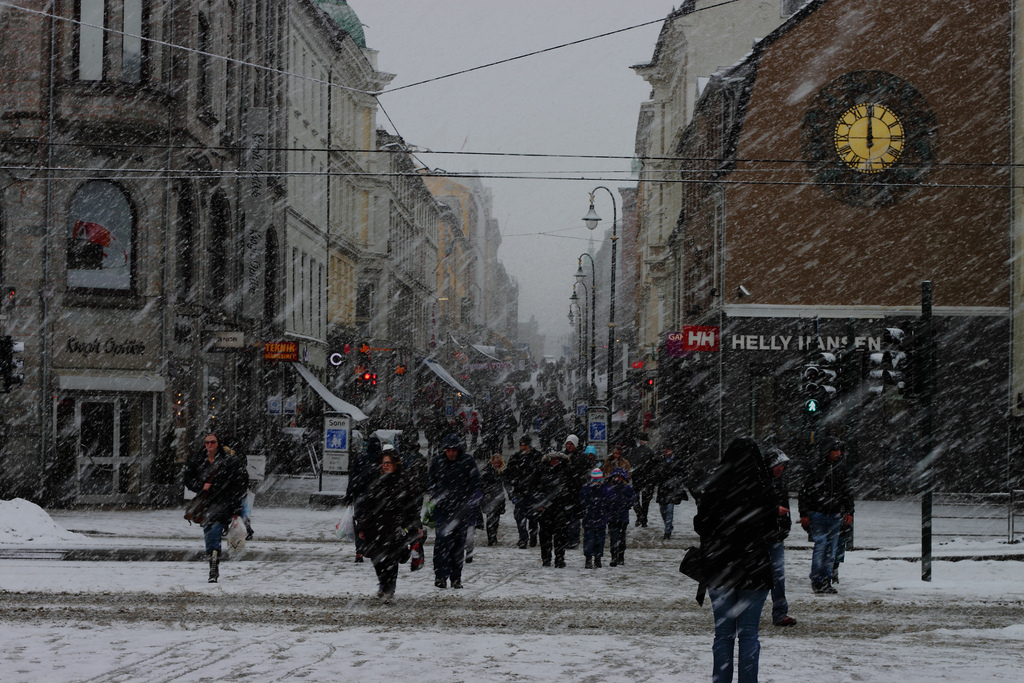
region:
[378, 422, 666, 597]
People walking across a snow covered street.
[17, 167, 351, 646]
Walking on a snowy day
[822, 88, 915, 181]
a yellow clock face with roman numerals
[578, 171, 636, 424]
a street light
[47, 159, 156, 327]
a rounded window in the snow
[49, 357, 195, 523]
shop doors in the snow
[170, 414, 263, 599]
a shopper in a black jacket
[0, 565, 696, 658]
tire tracks in the snow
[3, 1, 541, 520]
buildings on a snowy day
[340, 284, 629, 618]
shoppers on a busy street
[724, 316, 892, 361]
a shop sign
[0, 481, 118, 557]
a white pile of snow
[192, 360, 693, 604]
Groups of people walking in town on a snowy day.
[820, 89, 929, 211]
Clock face on the side of a building.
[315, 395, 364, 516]
Blue and white information sign.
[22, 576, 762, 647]
Vehicle tracks in the snow.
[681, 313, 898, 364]
Store sign in white lettering.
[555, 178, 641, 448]
Old style street light.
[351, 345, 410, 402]
Vehicle lights for traffic.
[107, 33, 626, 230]
Electrical cabling overhead the town street.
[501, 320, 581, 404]
Far side of the street down town.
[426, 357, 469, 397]
Fabric roofing for the front of a shop.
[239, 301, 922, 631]
many pedestrians on a city street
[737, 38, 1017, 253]
a clock on a store front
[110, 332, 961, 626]
people walking in a snowstorm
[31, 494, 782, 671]
snow on the ground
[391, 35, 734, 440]
a cloudy winter sky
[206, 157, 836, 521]
shops on a crowded city street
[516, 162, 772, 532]
lamp posts along a city street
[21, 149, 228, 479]
decorations in a store window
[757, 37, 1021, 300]
Twelve noon in the city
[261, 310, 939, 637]
shoppers braving a winter storm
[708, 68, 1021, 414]
Snow appears to be driving from right to left.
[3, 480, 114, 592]
One large drift of snow.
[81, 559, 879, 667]
Even pair of tracks in lightly fallen snow.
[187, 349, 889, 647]
Milling, rushing people in dark, winter clothes.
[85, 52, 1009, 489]
Elderly, brick buildings in grey, white and red.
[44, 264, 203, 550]
Store name in script and entryway.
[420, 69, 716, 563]
Perspective makes space between buildings appear to grow smaller in the distance.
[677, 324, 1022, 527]
Traffic light and two signs, reading "HH" and "Helly..."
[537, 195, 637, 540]
Grey day and line of cane-shaped street lights, one bulb each.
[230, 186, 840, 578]
Snow is falling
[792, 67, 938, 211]
Roman numerals are on a clock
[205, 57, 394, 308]
Windows on buildings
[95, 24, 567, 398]
Many buildings are next to each other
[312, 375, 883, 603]
Many people are walking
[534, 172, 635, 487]
Lamp posts are lined up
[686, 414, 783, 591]
Person has on a black coat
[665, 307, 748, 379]
A red sign reads "HH"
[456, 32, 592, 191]
Sky is very cloudy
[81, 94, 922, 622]
it's a snow storm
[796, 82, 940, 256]
vintage clock on the building wall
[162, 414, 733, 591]
people are crossing the street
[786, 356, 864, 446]
the walk sign is on green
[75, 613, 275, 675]
snow on the ground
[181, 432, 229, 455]
the woman is wearing shades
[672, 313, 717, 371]
a red flag has HH letter on it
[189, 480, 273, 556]
the woman is carrying bags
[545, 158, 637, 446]
lamp posts are off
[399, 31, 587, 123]
the sky is gray